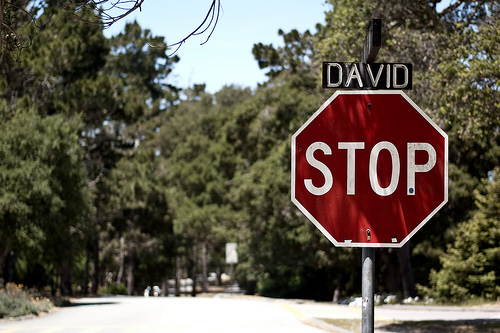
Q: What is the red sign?
A: Stop.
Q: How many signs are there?
A: Two.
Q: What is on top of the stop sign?
A: A sign.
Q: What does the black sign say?
A: David.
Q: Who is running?
A: No one.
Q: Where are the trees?
A: Both sides.